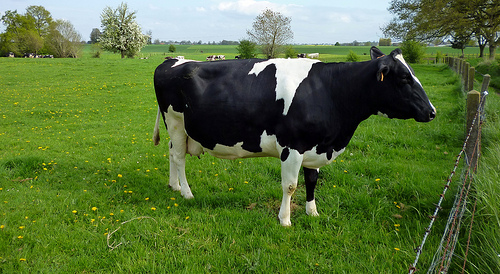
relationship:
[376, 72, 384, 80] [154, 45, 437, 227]
tag identifies cow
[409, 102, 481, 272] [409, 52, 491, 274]
barbed wire reinforces barbed wire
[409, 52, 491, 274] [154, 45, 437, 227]
barbed wire helps to pen cow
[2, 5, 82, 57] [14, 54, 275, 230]
trees outline field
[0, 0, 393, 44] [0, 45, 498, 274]
sky cushions field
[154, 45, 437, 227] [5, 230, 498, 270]
cow graze in pasture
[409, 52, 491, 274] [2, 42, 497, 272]
barbed wire marks end of pasture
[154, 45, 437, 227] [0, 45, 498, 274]
cow standing in field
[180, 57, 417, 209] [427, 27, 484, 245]
cow looking over fence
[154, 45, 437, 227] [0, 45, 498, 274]
cow waiting on field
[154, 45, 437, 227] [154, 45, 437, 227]
cow dignifies cow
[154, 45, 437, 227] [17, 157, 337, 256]
cow stands alone on grass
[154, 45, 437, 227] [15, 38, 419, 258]
cow makes his day on field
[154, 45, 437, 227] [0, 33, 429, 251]
cow stands in field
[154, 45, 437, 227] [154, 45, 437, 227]
cow on hide of cow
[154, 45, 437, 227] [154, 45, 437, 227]
cow marks cow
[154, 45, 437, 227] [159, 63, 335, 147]
cow marks hide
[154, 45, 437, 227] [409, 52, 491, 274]
cow avoids barbed wire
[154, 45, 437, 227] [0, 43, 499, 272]
cow in field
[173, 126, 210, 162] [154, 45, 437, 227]
udder on a cow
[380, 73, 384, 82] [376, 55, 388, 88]
tag in ear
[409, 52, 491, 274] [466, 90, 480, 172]
barbed wire with post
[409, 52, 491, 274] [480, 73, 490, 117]
barbed wire with post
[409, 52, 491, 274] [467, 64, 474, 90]
barbed wire with post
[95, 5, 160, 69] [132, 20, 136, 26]
tree with blooms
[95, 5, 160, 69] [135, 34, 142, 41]
tree with blooms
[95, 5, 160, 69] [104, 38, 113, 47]
tree with blooms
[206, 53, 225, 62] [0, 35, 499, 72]
cows in background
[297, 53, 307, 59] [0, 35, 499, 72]
cows in background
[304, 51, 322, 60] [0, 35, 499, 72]
cows in background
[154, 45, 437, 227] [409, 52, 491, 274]
cow inside barbed wire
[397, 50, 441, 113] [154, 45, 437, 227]
line on cow